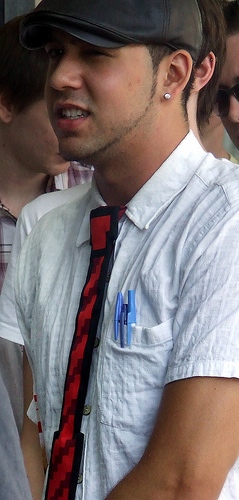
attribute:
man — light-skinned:
[32, 3, 214, 210]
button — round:
[83, 402, 92, 418]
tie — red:
[77, 207, 111, 296]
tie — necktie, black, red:
[41, 195, 135, 499]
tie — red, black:
[36, 200, 146, 415]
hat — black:
[14, 1, 201, 59]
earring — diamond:
[155, 81, 178, 104]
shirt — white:
[0, 132, 233, 498]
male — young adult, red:
[0, 4, 209, 240]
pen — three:
[112, 288, 119, 346]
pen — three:
[118, 303, 127, 344]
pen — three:
[124, 289, 137, 346]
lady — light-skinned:
[0, 13, 93, 293]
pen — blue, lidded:
[120, 301, 126, 345]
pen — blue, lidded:
[114, 291, 121, 340]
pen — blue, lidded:
[127, 289, 136, 345]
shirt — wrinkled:
[16, 165, 235, 496]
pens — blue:
[108, 286, 145, 346]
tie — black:
[42, 200, 120, 498]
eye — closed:
[81, 48, 113, 59]